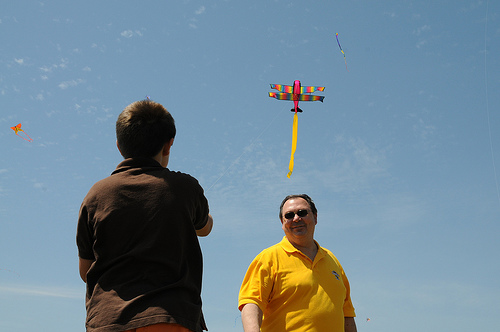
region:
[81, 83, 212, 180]
head of a person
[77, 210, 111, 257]
arm of a person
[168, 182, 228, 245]
arm of a person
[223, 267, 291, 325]
arm of a person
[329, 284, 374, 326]
arm of a person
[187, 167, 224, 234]
an arm of a person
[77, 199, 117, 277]
an arm of a person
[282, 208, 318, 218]
eye of a person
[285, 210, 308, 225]
nose of a person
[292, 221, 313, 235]
mouth of a person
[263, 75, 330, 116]
an airplane kite flying in the sky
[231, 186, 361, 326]
a man wearing a yellow shirt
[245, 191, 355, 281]
a man wearing a pair sunglass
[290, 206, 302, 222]
the nose of a man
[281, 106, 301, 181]
the tail of a kite plane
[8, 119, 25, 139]
a kite in the sky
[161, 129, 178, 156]
an ear of a man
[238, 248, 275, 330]
an arm of a man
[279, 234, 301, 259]
the collar of a yellow shirt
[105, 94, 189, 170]
the back of the head of a man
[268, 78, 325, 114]
a rainbow colored airplane kite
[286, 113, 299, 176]
the yellow tail of an airplane kite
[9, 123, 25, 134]
an orange butterfly kite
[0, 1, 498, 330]
a blue and white sky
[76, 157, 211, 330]
a brown shirt on a boy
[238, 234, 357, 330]
a yellow shirt on a man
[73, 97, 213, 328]
a boy looking at a kite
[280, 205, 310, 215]
sunglasses on a man's face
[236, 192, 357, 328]
a man watching a boy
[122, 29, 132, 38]
a very small white cloud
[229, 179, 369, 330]
this is a man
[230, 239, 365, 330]
man wearing a yellow shirt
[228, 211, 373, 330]
yellow shirt is a polo shirt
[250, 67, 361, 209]
this is a kite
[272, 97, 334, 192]
yellow tail on kite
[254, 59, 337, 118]
the kite is multicolored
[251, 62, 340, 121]
kite shaped like a plane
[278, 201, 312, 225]
a pair of black sunglasses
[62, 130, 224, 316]
person wearing a black shirt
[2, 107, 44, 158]
orange kite in sky